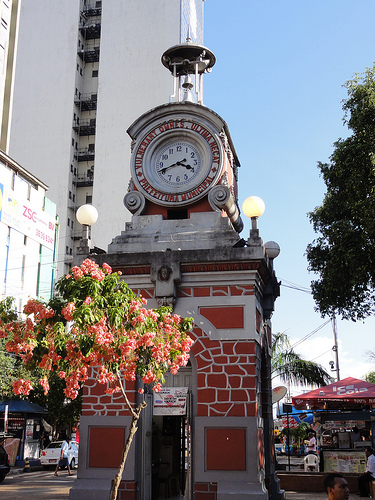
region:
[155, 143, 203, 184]
A clock on a tower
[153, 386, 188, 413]
A banner above a door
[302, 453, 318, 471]
Plastic white chair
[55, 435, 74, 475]
Man walking on the street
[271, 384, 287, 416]
Satellite dish on a pole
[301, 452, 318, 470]
A white chair on a side walk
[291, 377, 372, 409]
A vendors tent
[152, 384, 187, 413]
White poster above a door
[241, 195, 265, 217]
A light globe on a brick tower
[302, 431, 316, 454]
A person wearing a pink shirt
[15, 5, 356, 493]
a clock tower on a busy street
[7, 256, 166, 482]
a tree with blossoms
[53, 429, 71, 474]
woman crossing the street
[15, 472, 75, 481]
traffic lines in the road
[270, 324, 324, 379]
fronds of a palm tree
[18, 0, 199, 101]
tall white building behind the clock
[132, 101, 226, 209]
clock face of the tower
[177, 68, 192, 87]
bell on top of the tower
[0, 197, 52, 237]
billboard on the facade of the building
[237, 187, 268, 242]
light on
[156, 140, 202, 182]
a clock on the tower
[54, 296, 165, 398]
flowers next to the tower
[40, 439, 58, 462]
a car near the building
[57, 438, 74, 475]
a person crossing the road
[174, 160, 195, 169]
the hour hand of a clock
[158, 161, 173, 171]
the minute hand of a clock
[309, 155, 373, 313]
leaves of a tree near the tower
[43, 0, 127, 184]
a tall building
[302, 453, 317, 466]
a plastic chair near the tower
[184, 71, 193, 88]
a bell on top of the tower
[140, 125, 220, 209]
white face on clock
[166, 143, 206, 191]
black numbers on clock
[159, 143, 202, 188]
black hands on clock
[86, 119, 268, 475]
red and white monument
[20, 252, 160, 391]
red flowers in front of monument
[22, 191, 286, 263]
globe lights on monument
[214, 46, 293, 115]
sky is blue and clear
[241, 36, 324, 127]
no clouds in sky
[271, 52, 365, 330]
green tree on right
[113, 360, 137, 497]
thin and brown branch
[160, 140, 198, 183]
clock on the building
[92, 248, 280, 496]
building is red and white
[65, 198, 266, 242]
street lights on each side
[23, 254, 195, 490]
pink flowers on the tree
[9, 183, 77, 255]
billboard on the building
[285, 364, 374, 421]
ICE COLA written on tent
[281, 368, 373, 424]
red tent on side of tower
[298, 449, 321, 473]
plastic white chair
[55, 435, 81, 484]
man walking across the road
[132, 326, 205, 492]
door to the tower